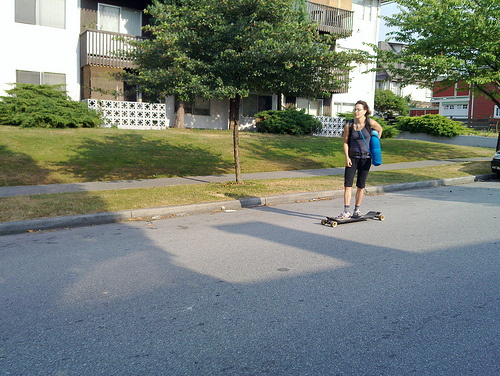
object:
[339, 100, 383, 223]
woman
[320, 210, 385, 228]
skateboard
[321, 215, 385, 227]
wheels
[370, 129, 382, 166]
bag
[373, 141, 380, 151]
blue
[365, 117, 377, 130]
shoulder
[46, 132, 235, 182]
shadow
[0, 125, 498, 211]
grass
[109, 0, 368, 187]
tree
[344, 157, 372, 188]
pants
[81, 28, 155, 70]
railing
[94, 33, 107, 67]
vertical slats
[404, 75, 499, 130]
building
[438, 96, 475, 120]
garage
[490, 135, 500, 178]
car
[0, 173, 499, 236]
curb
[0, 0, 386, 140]
building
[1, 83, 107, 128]
bush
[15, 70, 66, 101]
window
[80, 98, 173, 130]
white fence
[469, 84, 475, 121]
white trim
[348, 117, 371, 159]
shirt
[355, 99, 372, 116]
brown hair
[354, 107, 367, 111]
glasses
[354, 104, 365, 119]
face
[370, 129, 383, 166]
blue yoga mat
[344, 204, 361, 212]
gray socks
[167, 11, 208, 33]
leaves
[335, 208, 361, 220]
feet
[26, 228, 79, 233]
leaves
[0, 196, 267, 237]
side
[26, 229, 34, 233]
dry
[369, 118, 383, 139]
arm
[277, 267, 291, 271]
black spot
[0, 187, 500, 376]
surface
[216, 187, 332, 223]
shadow